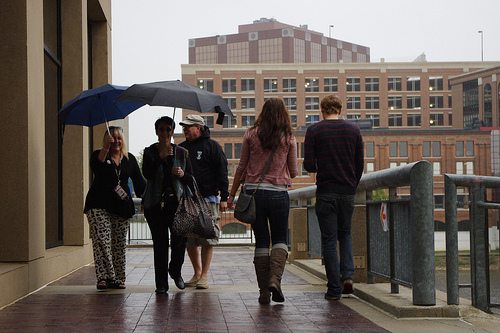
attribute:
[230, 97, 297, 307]
lady — wearing brown boots, supported by leg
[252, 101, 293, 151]
hair — dark, long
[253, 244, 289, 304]
knee high boots — tall, brown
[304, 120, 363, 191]
shirt — striped, long sleeved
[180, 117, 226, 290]
man — wearing cap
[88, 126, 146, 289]
lady — wearing printed pant, blond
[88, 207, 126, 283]
pants — print patterned, patterned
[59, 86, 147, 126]
umbrella — blue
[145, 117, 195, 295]
lady — holding bag, owner of the leg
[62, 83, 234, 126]
umbrellas — open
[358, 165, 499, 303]
railing — modern, metal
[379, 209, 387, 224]
arrow — directional arrow, red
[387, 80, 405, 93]
window — on building facade, in building, part of building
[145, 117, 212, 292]
man and lady — walking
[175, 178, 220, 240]
bag — big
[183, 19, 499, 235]
buildings — in background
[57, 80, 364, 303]
people — walking, on harbor, walking in rain, walking on sidewalk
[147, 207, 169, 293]
leg — on a person, part of a person, on a walking person, that of a person